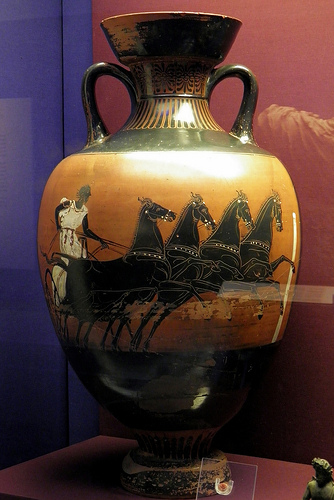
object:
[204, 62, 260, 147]
handle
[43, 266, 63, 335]
wheel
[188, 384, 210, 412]
refection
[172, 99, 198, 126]
refection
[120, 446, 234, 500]
base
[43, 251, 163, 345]
chariot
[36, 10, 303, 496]
pot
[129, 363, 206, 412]
area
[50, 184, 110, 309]
driver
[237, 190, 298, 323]
horse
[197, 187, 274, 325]
horse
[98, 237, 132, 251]
reins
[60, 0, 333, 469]
wall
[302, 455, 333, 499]
statue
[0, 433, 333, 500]
table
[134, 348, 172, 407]
patch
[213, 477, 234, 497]
item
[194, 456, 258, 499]
case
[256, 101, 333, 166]
picture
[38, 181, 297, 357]
drawings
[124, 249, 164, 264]
stripes